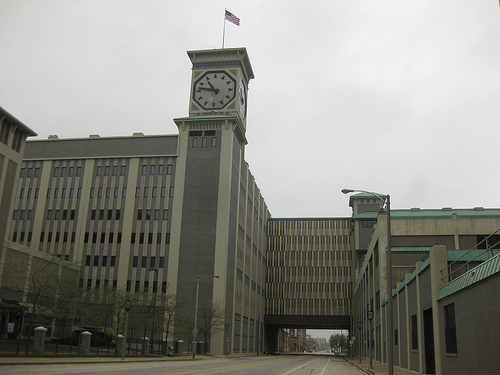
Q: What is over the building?
A: A cloudy sky.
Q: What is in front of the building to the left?
A: Trees.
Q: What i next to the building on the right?
A: A street light.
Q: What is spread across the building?
A: Many windows.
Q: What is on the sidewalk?
A: Trees.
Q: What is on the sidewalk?
A: Trees.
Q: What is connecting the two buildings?
A: A bridge walkway.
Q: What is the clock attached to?
A: A large gray building.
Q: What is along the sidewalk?
A: A fence.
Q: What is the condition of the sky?
A: Overcast.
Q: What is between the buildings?
A: A walkway between the buildings.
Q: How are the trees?
A: The trees are bare.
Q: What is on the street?
A: The street is empty.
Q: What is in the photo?
A: Buildings.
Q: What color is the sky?
A: Grey.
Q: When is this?
A: Daytime.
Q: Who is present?
A: No one.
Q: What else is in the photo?
A: Trees.